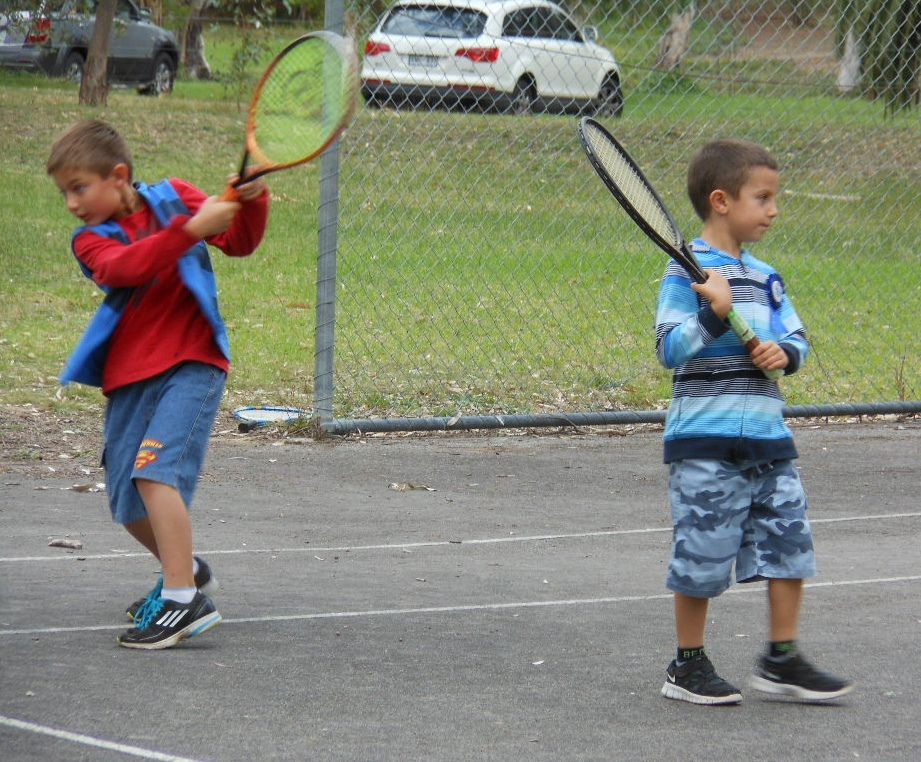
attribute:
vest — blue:
[66, 180, 228, 375]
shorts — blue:
[672, 452, 816, 606]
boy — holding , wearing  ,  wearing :
[670, 139, 850, 708]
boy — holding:
[5, 128, 276, 663]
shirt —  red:
[59, 216, 228, 373]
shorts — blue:
[95, 361, 220, 535]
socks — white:
[150, 572, 205, 605]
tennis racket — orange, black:
[227, 28, 381, 190]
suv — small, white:
[357, 3, 639, 120]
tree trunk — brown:
[70, 9, 126, 110]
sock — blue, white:
[156, 579, 202, 608]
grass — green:
[349, 132, 604, 367]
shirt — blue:
[649, 240, 809, 475]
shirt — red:
[71, 175, 263, 382]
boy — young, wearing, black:
[38, 125, 272, 644]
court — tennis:
[38, 417, 915, 758]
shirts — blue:
[73, 177, 198, 377]